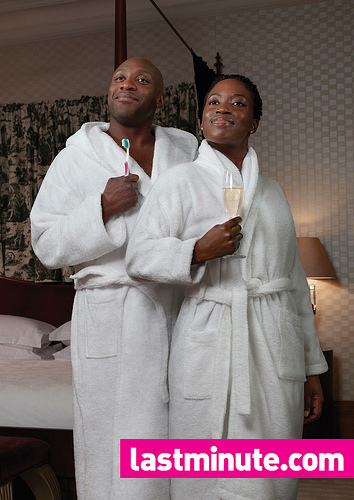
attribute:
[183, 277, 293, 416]
bathrobe belt — white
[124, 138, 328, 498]
bathrobe — white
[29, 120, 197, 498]
bathrobe — white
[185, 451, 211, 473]
letter — white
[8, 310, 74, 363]
pillows — white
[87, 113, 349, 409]
bathrobe — white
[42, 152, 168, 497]
robe — white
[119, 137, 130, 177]
toothbrush — pink, white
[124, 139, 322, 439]
robe — white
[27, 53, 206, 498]
man — black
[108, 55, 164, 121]
head — bald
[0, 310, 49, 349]
pillow — white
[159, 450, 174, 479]
letter — white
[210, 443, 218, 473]
letter — white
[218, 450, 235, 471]
letter — white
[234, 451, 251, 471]
letter — white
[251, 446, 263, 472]
letter — white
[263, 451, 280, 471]
letter — white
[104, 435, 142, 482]
letter — white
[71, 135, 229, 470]
bathrobe — white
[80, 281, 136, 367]
pocket — rectangular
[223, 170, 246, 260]
glass — clear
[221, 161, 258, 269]
glass — champagne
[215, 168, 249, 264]
glass — wine